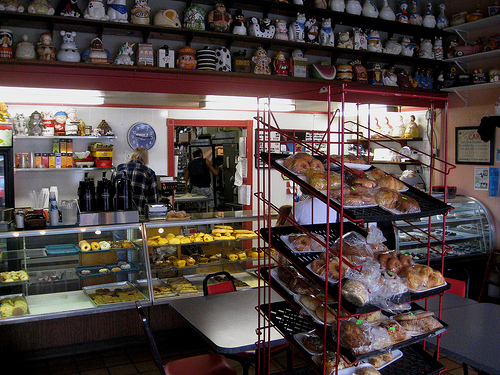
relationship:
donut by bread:
[329, 257, 348, 278] [407, 267, 446, 293]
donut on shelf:
[329, 257, 348, 278] [264, 220, 450, 312]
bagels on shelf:
[277, 149, 332, 174] [268, 150, 450, 230]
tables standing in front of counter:
[438, 289, 498, 369] [8, 210, 260, 229]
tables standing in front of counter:
[438, 289, 498, 369] [8, 219, 261, 284]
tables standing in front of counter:
[438, 289, 498, 369] [188, 210, 252, 217]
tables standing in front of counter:
[166, 286, 288, 356] [8, 210, 260, 229]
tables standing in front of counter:
[166, 286, 288, 356] [8, 219, 261, 284]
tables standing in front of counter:
[166, 286, 288, 356] [188, 210, 252, 217]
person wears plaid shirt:
[109, 145, 161, 282] [115, 157, 160, 216]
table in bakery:
[168, 285, 285, 350] [24, 25, 477, 367]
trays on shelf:
[265, 209, 402, 299] [254, 142, 338, 312]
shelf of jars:
[0, 0, 465, 108] [0, 0, 447, 93]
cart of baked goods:
[265, 131, 435, 368] [276, 146, 447, 370]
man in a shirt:
[183, 148, 220, 212] [189, 158, 213, 188]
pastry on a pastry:
[79, 241, 91, 254] [164, 236, 183, 246]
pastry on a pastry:
[79, 241, 91, 254] [226, 252, 239, 263]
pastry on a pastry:
[79, 241, 91, 254] [89, 240, 101, 250]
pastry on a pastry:
[79, 241, 91, 254] [97, 238, 111, 252]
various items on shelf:
[2, 3, 402, 82] [232, 57, 377, 97]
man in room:
[182, 146, 220, 212] [175, 126, 242, 210]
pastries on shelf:
[226, 80, 448, 365] [12, 241, 270, 314]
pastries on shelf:
[226, 80, 448, 365] [8, 10, 465, 105]